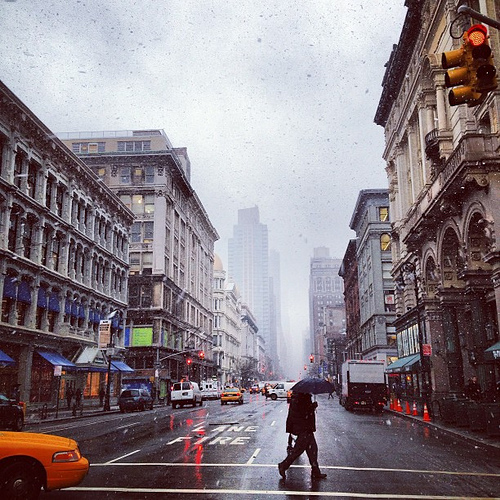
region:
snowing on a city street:
[92, 93, 367, 448]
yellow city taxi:
[2, 415, 95, 499]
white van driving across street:
[265, 376, 308, 408]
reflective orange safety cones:
[382, 389, 458, 436]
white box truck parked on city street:
[335, 358, 404, 426]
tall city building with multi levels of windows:
[22, 164, 139, 469]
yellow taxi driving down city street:
[214, 383, 254, 418]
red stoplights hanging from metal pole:
[158, 342, 216, 432]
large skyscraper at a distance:
[222, 190, 317, 385]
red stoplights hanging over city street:
[290, 341, 340, 379]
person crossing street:
[262, 364, 352, 486]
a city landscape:
[106, 4, 483, 485]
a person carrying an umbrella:
[266, 361, 353, 494]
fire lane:
[171, 408, 286, 497]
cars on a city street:
[162, 355, 400, 427]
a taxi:
[4, 407, 126, 497]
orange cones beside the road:
[381, 385, 478, 447]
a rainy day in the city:
[31, 8, 454, 453]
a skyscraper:
[222, 198, 292, 383]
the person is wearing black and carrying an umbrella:
[262, 363, 386, 472]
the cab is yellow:
[3, 428, 101, 495]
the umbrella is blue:
[288, 374, 356, 397]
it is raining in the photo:
[13, 223, 458, 493]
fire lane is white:
[185, 418, 257, 448]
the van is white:
[171, 378, 209, 401]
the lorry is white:
[336, 356, 393, 408]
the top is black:
[281, 399, 332, 436]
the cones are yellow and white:
[395, 398, 445, 428]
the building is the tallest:
[235, 215, 310, 349]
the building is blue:
[41, 352, 94, 369]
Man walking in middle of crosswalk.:
[269, 374, 335, 483]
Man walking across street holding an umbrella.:
[240, 372, 375, 484]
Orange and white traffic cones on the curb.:
[384, 397, 434, 426]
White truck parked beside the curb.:
[340, 357, 390, 417]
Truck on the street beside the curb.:
[340, 357, 430, 439]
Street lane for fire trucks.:
[107, 407, 273, 496]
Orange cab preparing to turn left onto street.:
[0, 422, 93, 498]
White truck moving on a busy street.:
[265, 375, 307, 403]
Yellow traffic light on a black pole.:
[435, 7, 498, 105]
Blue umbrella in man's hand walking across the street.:
[286, 375, 336, 407]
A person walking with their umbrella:
[265, 356, 345, 496]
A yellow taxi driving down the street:
[206, 376, 256, 415]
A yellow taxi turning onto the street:
[2, 416, 118, 498]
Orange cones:
[376, 386, 445, 444]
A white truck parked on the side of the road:
[325, 344, 401, 421]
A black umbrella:
[289, 371, 351, 403]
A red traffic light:
[296, 348, 325, 367]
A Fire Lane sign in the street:
[160, 401, 267, 472]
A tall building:
[196, 174, 324, 389]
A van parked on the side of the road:
[101, 374, 162, 427]